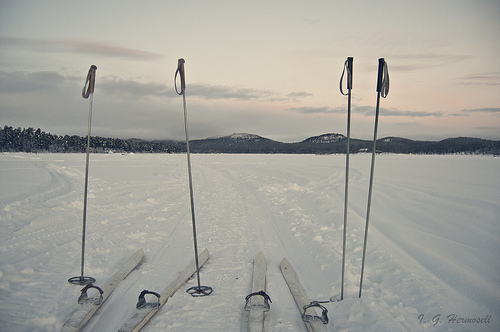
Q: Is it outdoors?
A: Yes, it is outdoors.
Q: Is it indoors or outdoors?
A: It is outdoors.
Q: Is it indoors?
A: No, it is outdoors.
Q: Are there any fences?
A: No, there are no fences.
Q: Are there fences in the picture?
A: No, there are no fences.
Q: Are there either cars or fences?
A: No, there are no fences or cars.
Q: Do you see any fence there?
A: No, there are no fences.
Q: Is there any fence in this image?
A: No, there are no fences.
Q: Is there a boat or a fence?
A: No, there are no fences or boats.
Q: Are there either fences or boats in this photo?
A: No, there are no fences or boats.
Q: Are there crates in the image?
A: No, there are no crates.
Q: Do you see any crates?
A: No, there are no crates.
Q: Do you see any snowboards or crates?
A: No, there are no crates or snowboards.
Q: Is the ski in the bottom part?
A: Yes, the ski is in the bottom of the image.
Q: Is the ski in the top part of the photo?
A: No, the ski is in the bottom of the image.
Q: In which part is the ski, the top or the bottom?
A: The ski is in the bottom of the image.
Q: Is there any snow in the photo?
A: Yes, there is snow.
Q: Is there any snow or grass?
A: Yes, there is snow.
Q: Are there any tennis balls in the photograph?
A: No, there are no tennis balls.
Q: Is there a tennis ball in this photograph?
A: No, there are no tennis balls.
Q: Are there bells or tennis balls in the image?
A: No, there are no tennis balls or bells.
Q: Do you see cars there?
A: No, there are no cars.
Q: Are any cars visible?
A: No, there are no cars.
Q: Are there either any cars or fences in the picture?
A: No, there are no cars or fences.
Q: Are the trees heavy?
A: Yes, the trees are heavy.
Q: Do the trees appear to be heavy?
A: Yes, the trees are heavy.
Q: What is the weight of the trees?
A: The trees are heavy.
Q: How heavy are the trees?
A: The trees are heavy.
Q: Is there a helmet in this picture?
A: No, there are no helmets.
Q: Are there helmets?
A: No, there are no helmets.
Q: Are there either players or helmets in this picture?
A: No, there are no helmets or players.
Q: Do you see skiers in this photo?
A: No, there are no skiers.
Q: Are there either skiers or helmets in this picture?
A: No, there are no skiers or helmets.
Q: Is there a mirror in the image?
A: No, there are no mirrors.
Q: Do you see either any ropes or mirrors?
A: No, there are no mirrors or ropes.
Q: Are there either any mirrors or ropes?
A: No, there are no mirrors or ropes.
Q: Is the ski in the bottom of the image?
A: Yes, the ski is in the bottom of the image.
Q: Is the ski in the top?
A: No, the ski is in the bottom of the image.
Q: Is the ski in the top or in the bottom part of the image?
A: The ski is in the bottom of the image.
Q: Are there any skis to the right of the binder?
A: Yes, there is a ski to the right of the binder.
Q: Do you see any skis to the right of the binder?
A: Yes, there is a ski to the right of the binder.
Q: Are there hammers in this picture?
A: No, there are no hammers.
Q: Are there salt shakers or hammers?
A: No, there are no hammers or salt shakers.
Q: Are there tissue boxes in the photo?
A: No, there are no tissue boxes.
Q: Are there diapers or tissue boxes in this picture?
A: No, there are no tissue boxes or diapers.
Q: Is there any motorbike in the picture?
A: No, there are no motorcycles.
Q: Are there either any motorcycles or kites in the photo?
A: No, there are no motorcycles or kites.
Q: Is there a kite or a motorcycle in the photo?
A: No, there are no motorcycles or kites.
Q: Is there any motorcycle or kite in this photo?
A: No, there are no motorcycles or kites.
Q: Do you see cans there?
A: No, there are no cans.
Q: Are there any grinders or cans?
A: No, there are no cans or grinders.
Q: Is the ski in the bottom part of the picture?
A: Yes, the ski is in the bottom of the image.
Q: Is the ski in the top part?
A: No, the ski is in the bottom of the image.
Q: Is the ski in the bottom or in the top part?
A: The ski is in the bottom of the image.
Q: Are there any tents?
A: No, there are no tents.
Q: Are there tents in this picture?
A: No, there are no tents.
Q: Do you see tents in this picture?
A: No, there are no tents.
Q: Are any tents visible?
A: No, there are no tents.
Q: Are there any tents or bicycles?
A: No, there are no tents or bicycles.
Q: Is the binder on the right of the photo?
A: No, the binder is on the left of the image.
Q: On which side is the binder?
A: The binder is on the left of the image.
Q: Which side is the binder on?
A: The binder is on the left of the image.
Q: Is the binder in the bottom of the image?
A: Yes, the binder is in the bottom of the image.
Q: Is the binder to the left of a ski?
A: Yes, the binder is to the left of a ski.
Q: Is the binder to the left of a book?
A: No, the binder is to the left of a ski.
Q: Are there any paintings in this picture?
A: No, there are no paintings.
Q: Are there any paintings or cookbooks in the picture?
A: No, there are no paintings or cookbooks.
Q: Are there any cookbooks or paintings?
A: No, there are no paintings or cookbooks.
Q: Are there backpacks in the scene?
A: No, there are no backpacks.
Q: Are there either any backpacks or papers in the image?
A: No, there are no backpacks or papers.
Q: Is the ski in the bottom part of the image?
A: Yes, the ski is in the bottom of the image.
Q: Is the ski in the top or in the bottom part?
A: The ski is in the bottom of the image.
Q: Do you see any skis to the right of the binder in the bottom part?
A: Yes, there is a ski to the right of the binder.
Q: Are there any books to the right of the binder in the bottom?
A: No, there is a ski to the right of the binder.